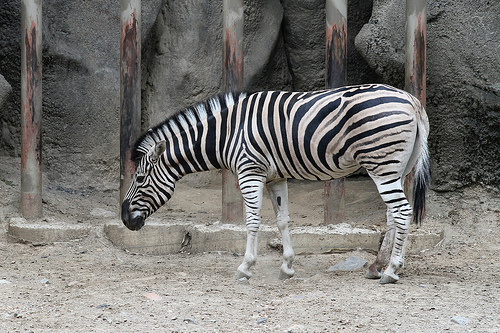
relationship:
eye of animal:
[132, 169, 150, 186] [118, 82, 434, 284]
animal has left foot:
[118, 82, 434, 284] [380, 267, 404, 283]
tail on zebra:
[409, 111, 452, 225] [103, 75, 484, 304]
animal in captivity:
[118, 82, 434, 284] [3, 1, 494, 331]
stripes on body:
[173, 119, 387, 154] [225, 85, 402, 191]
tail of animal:
[412, 112, 430, 227] [118, 82, 434, 284]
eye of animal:
[136, 175, 147, 183] [118, 82, 434, 284]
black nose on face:
[119, 193, 166, 233] [105, 147, 189, 215]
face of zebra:
[105, 147, 189, 215] [67, 76, 430, 282]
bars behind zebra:
[19, 0, 45, 222] [88, 78, 440, 295]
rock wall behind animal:
[430, 1, 499, 104] [118, 82, 434, 284]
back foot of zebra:
[382, 266, 400, 286] [84, 67, 468, 294]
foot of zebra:
[232, 264, 257, 281] [81, 56, 496, 323]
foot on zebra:
[231, 247, 261, 288] [135, 95, 344, 225]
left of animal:
[151, 130, 171, 161] [118, 82, 434, 284]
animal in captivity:
[118, 78, 440, 290] [3, 1, 494, 331]